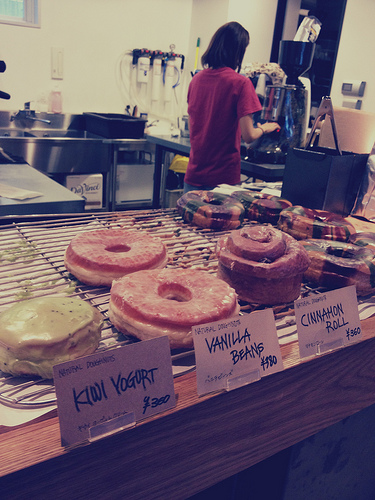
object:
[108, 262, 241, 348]
doughnut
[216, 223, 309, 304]
cinnamon roll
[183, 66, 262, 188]
tshirt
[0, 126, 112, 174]
sink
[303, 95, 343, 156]
tongs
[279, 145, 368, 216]
container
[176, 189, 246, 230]
donut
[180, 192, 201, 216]
chocolate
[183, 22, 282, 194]
girl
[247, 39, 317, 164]
coffeemaker